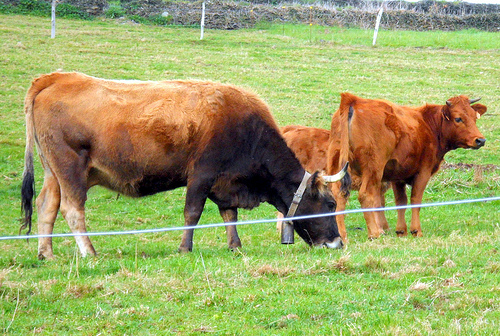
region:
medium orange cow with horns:
[332, 86, 488, 237]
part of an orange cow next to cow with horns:
[281, 120, 333, 231]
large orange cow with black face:
[4, 66, 356, 266]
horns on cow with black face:
[303, 158, 353, 179]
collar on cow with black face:
[285, 168, 311, 223]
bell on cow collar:
[278, 217, 296, 247]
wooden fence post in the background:
[196, 1, 209, 38]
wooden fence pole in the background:
[368, 4, 383, 51]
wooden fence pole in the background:
[47, 0, 59, 39]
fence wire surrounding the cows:
[1, 193, 498, 244]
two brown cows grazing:
[279, 35, 490, 283]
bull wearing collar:
[16, 27, 353, 258]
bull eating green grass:
[2, 47, 355, 281]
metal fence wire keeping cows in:
[0, 179, 493, 255]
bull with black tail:
[8, 88, 58, 258]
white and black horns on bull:
[302, 147, 367, 194]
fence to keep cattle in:
[8, 0, 471, 45]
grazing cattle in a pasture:
[14, 57, 493, 280]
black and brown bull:
[19, 67, 349, 262]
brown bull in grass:
[326, 91, 490, 240]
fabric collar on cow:
[287, 166, 311, 221]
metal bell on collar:
[281, 219, 296, 243]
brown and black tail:
[7, 81, 39, 229]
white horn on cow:
[319, 162, 351, 183]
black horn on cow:
[471, 93, 480, 103]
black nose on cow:
[474, 136, 486, 148]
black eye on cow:
[456, 116, 463, 123]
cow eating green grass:
[13, 68, 350, 256]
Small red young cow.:
[332, 90, 490, 242]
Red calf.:
[321, 95, 487, 242]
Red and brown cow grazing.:
[21, 70, 348, 257]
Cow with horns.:
[279, 159, 352, 252]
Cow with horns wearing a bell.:
[278, 159, 351, 251]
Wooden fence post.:
[370, 3, 385, 45]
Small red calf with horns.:
[333, 93, 488, 233]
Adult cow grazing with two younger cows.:
[18, 73, 488, 260]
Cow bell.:
[280, 218, 295, 243]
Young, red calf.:
[325, 91, 485, 241]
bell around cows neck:
[278, 161, 305, 253]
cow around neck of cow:
[279, 162, 307, 251]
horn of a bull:
[464, 91, 484, 106]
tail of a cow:
[15, 85, 42, 233]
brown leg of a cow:
[179, 145, 199, 247]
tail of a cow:
[333, 91, 361, 182]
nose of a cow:
[468, 133, 487, 150]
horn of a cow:
[318, 159, 352, 186]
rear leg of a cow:
[359, 141, 390, 241]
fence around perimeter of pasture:
[33, 5, 498, 44]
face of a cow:
[428, 81, 492, 157]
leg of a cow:
[404, 175, 430, 238]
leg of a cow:
[359, 179, 383, 241]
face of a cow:
[285, 177, 347, 251]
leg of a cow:
[208, 203, 245, 253]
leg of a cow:
[161, 202, 204, 248]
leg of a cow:
[58, 192, 108, 263]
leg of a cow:
[28, 173, 56, 256]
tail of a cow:
[3, 87, 43, 253]